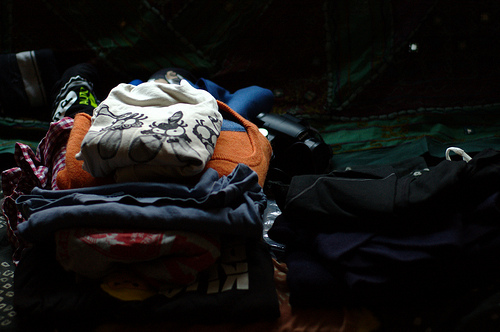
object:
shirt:
[11, 253, 272, 329]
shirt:
[75, 79, 223, 183]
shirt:
[0, 117, 74, 267]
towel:
[15, 163, 266, 245]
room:
[0, 2, 498, 329]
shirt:
[265, 150, 499, 319]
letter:
[222, 263, 249, 291]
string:
[445, 147, 473, 164]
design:
[77, 232, 177, 249]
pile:
[0, 70, 332, 284]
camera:
[256, 112, 335, 162]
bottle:
[258, 128, 270, 139]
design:
[53, 75, 98, 122]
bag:
[325, 7, 481, 108]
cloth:
[0, 69, 500, 330]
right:
[356, 51, 500, 265]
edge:
[71, 217, 171, 229]